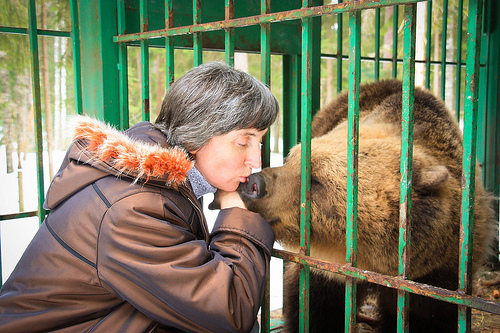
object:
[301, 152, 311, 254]
green paint1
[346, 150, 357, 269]
green paint2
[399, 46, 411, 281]
green paint3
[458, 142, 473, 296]
green paint4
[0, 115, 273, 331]
coat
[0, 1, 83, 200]
trees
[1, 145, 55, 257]
snow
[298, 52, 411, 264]
bars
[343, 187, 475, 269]
green bars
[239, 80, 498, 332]
bear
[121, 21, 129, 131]
metal bars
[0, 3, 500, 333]
cage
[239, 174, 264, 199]
nose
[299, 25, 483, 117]
metal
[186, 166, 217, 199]
collar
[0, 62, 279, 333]
man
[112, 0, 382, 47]
rusted rail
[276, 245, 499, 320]
rusted rail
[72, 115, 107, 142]
fur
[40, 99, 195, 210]
hood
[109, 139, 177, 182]
fur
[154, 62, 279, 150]
grey/black hair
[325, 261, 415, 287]
rust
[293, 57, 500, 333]
enclosure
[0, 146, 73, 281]
ground